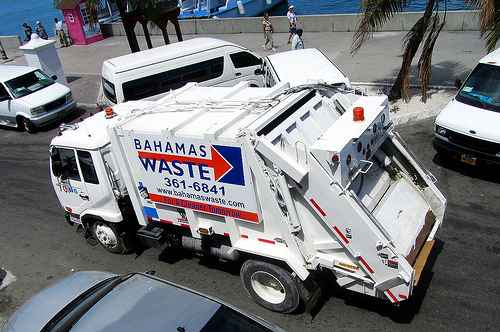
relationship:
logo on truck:
[132, 135, 245, 194] [48, 78, 450, 317]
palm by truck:
[387, 2, 448, 104] [48, 78, 450, 317]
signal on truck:
[102, 106, 117, 119] [48, 78, 450, 317]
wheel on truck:
[239, 255, 301, 316] [48, 78, 450, 317]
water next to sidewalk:
[2, 1, 490, 40] [18, 34, 493, 87]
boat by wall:
[175, 0, 281, 19] [101, 10, 494, 35]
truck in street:
[48, 78, 450, 317] [0, 113, 499, 331]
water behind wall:
[2, 1, 490, 40] [101, 10, 494, 35]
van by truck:
[1, 64, 80, 133] [48, 78, 450, 317]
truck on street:
[48, 78, 450, 317] [0, 113, 499, 331]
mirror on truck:
[45, 144, 65, 180] [48, 78, 450, 317]